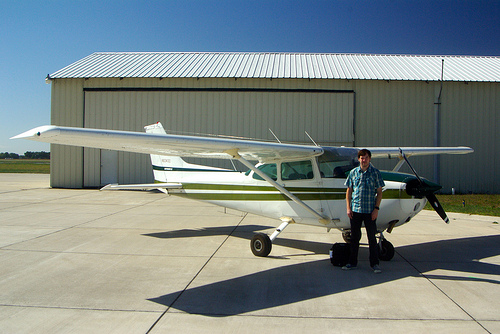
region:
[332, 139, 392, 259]
a man standing in front of an airplane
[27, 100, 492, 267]
a white airplane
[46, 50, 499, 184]
an airplane hangar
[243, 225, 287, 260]
the black airplane tiger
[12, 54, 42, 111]
a clear blue sky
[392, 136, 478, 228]
the airplane propeller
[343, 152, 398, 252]
a man wearing a blue and white plaid shirt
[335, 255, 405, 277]
a pair of shoes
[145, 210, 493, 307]
the shawdow of the airlane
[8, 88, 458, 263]
a man getting ready to fly an airplane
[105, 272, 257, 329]
long shadow cast on the ground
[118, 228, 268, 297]
line in the pavement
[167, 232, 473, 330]
large square on the tarmac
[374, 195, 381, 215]
black watch on man's hand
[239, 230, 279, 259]
small black and silver wheel on plane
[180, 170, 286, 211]
green lines on white plane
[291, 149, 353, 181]
large window in plane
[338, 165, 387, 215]
blue and green square shirt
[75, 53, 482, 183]
large door on building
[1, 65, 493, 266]
small plane on the ground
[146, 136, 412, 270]
the plane is white with stripes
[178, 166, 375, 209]
the airplane has two green stripes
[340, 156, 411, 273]
man standing next to airplane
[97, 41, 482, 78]
the roof is metal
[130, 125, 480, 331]
airplane on the cement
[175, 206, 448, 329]
the shadow of the airplane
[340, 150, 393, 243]
man is wearing a plaid shirt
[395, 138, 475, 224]
propeller of the plane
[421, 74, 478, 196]
metal pipe on the building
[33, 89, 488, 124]
the building is metal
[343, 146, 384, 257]
man standing next to airplane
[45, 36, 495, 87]
white roof of airplane hanger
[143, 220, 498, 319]
shadow of plane on the ground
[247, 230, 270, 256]
right wheel of airplane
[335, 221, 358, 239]
left wheel of plane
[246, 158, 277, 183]
right back window of plane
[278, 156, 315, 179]
front passenger window on right side of plane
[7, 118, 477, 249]
plane sitting on concrete ground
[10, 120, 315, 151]
right wing of plane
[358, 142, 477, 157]
left wing of plane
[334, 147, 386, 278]
this is a man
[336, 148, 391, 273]
the man is posing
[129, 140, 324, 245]
this is a plane beside the man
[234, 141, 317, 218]
the plane is white in color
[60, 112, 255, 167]
this is the wing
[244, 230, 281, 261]
this is the wheel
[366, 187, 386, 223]
the hand is on the lap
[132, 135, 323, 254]
the plane is motionless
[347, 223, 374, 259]
the jeans is black in color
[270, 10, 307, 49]
the sky is clear